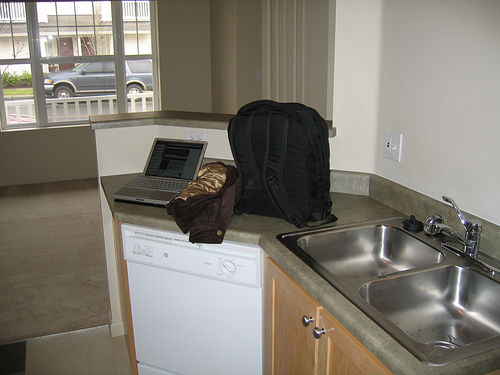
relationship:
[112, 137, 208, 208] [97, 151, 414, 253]
computer on counter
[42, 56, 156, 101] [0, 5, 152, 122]
car outside window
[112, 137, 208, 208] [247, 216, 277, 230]
computer on counter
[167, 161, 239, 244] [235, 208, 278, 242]
coat on counter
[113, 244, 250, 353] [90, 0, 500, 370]
dishwasher in kitchen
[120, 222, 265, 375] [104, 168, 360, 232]
dishwasher under counter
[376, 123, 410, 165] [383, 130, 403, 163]
outlet with outlet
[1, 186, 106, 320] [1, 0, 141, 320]
carpet in living room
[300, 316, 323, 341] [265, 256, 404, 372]
hardware on cabinets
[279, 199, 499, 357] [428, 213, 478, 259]
sink has faucet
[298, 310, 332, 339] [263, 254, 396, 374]
knobs on cabinets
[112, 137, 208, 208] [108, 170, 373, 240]
computer on counter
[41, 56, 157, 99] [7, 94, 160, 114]
car parked on road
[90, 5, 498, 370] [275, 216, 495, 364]
kitchen with sink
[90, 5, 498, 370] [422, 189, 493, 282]
kitchen with faucet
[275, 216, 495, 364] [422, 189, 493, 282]
sink with faucet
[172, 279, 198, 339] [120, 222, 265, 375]
part of a dishwasher